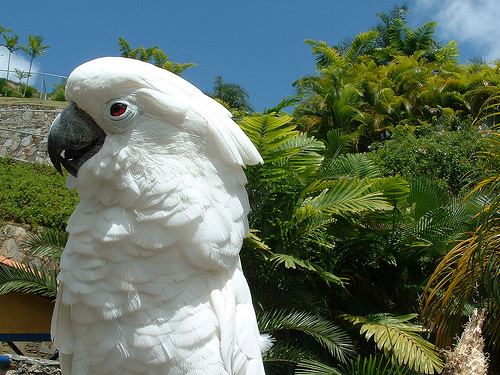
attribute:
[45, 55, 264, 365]
parrot — white, cockatoo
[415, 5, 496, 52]
clouds — white, puffy, small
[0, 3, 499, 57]
sky — blue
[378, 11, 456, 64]
tree — palm, tall, green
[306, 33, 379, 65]
tree — palm, tall, green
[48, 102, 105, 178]
beak — black, curved, open, pointy, sharp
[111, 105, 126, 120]
eye — red, black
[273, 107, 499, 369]
bushes — tropical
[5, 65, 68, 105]
fence — silver, chain link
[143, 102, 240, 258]
feathers — white, ruffled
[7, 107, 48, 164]
wall — stone, rock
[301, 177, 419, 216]
leaves — green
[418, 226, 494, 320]
leaves — yellow, palm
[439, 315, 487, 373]
straw — tan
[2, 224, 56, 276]
wall — rock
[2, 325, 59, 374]
ladder — blue, metal